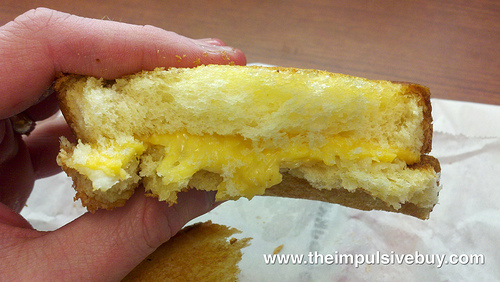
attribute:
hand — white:
[3, 3, 245, 281]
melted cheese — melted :
[81, 126, 423, 193]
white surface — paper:
[23, 65, 497, 281]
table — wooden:
[0, 0, 499, 107]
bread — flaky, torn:
[137, 225, 253, 282]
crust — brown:
[403, 83, 440, 217]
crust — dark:
[55, 75, 83, 212]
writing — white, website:
[259, 248, 490, 269]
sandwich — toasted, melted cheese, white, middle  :
[64, 63, 449, 214]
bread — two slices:
[64, 74, 444, 220]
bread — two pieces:
[55, 60, 441, 215]